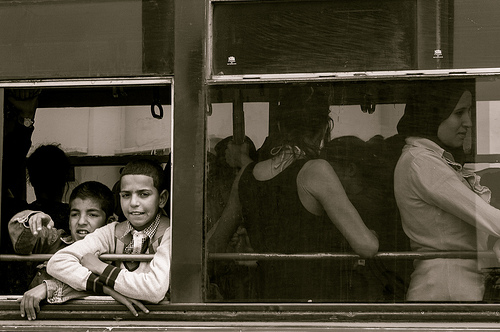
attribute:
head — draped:
[394, 75, 476, 150]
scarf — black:
[393, 76, 473, 169]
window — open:
[2, 85, 170, 307]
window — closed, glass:
[206, 87, 497, 302]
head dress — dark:
[396, 80, 473, 140]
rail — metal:
[205, 249, 499, 269]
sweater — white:
[49, 223, 179, 312]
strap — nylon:
[149, 102, 164, 120]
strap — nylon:
[203, 99, 211, 115]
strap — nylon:
[356, 99, 368, 112]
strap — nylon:
[367, 100, 375, 115]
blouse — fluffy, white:
[391, 131, 498, 267]